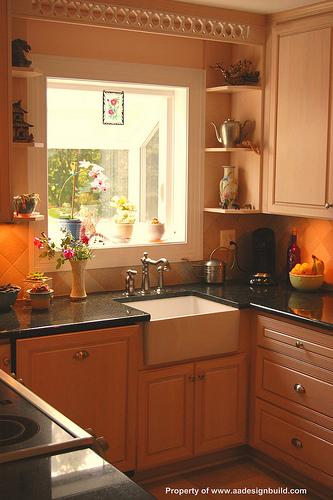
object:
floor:
[143, 457, 333, 500]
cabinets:
[16, 326, 135, 473]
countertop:
[252, 275, 333, 329]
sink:
[122, 294, 242, 367]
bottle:
[287, 226, 301, 285]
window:
[49, 72, 201, 256]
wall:
[127, 39, 204, 64]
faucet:
[123, 251, 171, 295]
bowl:
[289, 274, 326, 295]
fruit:
[290, 255, 325, 276]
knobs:
[293, 383, 306, 395]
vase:
[219, 162, 239, 209]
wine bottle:
[287, 228, 302, 285]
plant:
[111, 195, 137, 225]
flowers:
[33, 229, 93, 270]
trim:
[159, 17, 250, 36]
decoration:
[103, 89, 125, 125]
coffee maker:
[252, 228, 277, 275]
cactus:
[114, 210, 135, 224]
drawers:
[257, 313, 333, 374]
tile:
[182, 477, 210, 498]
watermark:
[161, 484, 306, 494]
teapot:
[211, 118, 253, 150]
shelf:
[205, 207, 259, 222]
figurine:
[209, 55, 261, 84]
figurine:
[11, 37, 33, 70]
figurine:
[9, 101, 34, 145]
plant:
[15, 195, 37, 215]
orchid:
[77, 168, 109, 201]